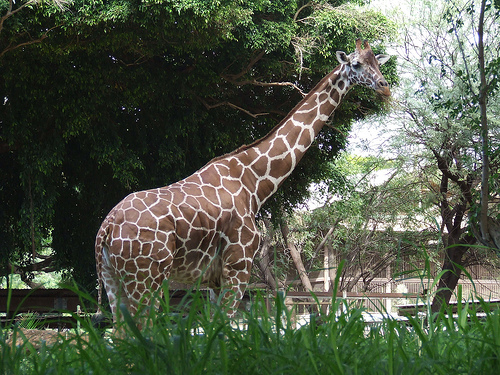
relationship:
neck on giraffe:
[214, 63, 354, 216] [95, 39, 390, 346]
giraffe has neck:
[95, 39, 390, 346] [214, 63, 354, 216]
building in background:
[167, 157, 498, 314] [0, 1, 499, 326]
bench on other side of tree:
[397, 300, 498, 325] [421, 1, 498, 325]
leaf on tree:
[266, 50, 269, 53] [0, 0, 400, 288]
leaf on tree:
[226, 30, 227, 31] [0, 0, 400, 288]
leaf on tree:
[103, 18, 106, 20] [0, 0, 400, 288]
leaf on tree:
[249, 12, 251, 14] [0, 0, 400, 288]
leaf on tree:
[48, 13, 49, 16] [0, 0, 400, 288]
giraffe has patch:
[95, 39, 390, 346] [178, 203, 196, 223]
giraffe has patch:
[95, 39, 390, 346] [222, 178, 242, 194]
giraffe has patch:
[95, 39, 390, 346] [139, 228, 155, 243]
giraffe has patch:
[95, 39, 390, 346] [149, 198, 170, 217]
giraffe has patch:
[95, 39, 390, 346] [185, 228, 208, 251]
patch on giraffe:
[139, 228, 155, 243] [95, 39, 390, 346]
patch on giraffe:
[149, 198, 170, 217] [95, 39, 390, 346]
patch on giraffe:
[178, 203, 196, 223] [95, 39, 390, 346]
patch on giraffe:
[185, 228, 208, 251] [95, 39, 390, 346]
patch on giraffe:
[222, 178, 242, 194] [95, 39, 390, 346]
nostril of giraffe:
[380, 82, 383, 87] [95, 39, 390, 346]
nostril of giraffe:
[384, 82, 387, 86] [95, 39, 390, 346]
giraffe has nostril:
[95, 39, 390, 346] [380, 82, 383, 87]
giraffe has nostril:
[95, 39, 390, 346] [384, 82, 387, 86]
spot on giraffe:
[185, 228, 208, 251] [95, 39, 390, 346]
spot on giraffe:
[149, 198, 170, 217] [95, 39, 390, 346]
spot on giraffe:
[139, 228, 155, 243] [95, 39, 390, 346]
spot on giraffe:
[222, 178, 242, 194] [95, 39, 390, 346]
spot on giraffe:
[178, 203, 196, 223] [95, 39, 390, 346]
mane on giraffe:
[197, 63, 341, 184] [95, 39, 390, 346]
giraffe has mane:
[95, 39, 390, 346] [197, 63, 341, 184]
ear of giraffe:
[335, 50, 350, 65] [95, 39, 390, 346]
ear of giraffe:
[375, 54, 390, 64] [95, 39, 390, 346]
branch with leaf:
[292, 1, 327, 21] [314, 1, 316, 3]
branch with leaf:
[432, 55, 481, 104] [455, 70, 461, 76]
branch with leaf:
[432, 55, 481, 104] [465, 86, 468, 90]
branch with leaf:
[432, 55, 481, 104] [471, 96, 475, 100]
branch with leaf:
[432, 55, 481, 104] [432, 56, 436, 60]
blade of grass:
[405, 312, 433, 359] [1, 217, 499, 374]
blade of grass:
[387, 320, 394, 374] [1, 217, 499, 374]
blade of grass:
[300, 328, 318, 374] [1, 217, 499, 374]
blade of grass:
[219, 340, 225, 374] [1, 217, 499, 374]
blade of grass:
[73, 344, 98, 374] [1, 217, 499, 374]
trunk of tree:
[422, 278, 459, 326] [392, 0, 499, 324]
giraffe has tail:
[95, 39, 390, 346] [94, 216, 110, 315]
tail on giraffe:
[94, 216, 110, 315] [95, 39, 390, 346]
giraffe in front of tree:
[95, 39, 390, 346] [0, 0, 400, 288]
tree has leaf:
[0, 0, 400, 288] [266, 50, 269, 53]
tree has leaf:
[0, 0, 400, 288] [249, 12, 251, 14]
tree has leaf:
[0, 0, 400, 288] [226, 30, 227, 31]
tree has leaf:
[0, 0, 400, 288] [103, 18, 106, 20]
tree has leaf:
[0, 0, 400, 288] [48, 13, 49, 16]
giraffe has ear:
[95, 39, 390, 346] [335, 50, 350, 65]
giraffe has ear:
[95, 39, 390, 346] [375, 54, 390, 64]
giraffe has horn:
[95, 39, 390, 346] [356, 39, 362, 51]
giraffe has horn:
[95, 39, 390, 346] [362, 40, 368, 49]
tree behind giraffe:
[0, 0, 400, 288] [95, 39, 390, 346]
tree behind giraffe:
[392, 0, 499, 324] [95, 39, 390, 346]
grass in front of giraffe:
[1, 217, 499, 374] [95, 39, 390, 346]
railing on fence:
[1, 289, 427, 299] [0, 288, 429, 312]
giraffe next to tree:
[95, 39, 390, 346] [421, 1, 498, 325]